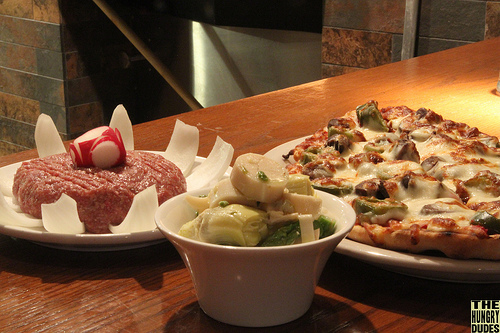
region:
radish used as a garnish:
[69, 118, 131, 171]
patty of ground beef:
[8, 148, 189, 223]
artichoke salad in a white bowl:
[152, 150, 357, 323]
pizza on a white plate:
[246, 87, 496, 284]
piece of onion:
[38, 188, 84, 239]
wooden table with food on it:
[0, 27, 497, 332]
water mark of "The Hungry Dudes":
[471, 300, 499, 332]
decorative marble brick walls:
[0, 3, 117, 153]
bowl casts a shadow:
[148, 290, 383, 332]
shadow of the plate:
[4, 230, 192, 295]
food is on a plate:
[4, 113, 233, 231]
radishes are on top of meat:
[72, 124, 118, 166]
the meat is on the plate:
[20, 143, 178, 225]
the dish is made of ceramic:
[157, 150, 356, 329]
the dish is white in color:
[153, 177, 352, 326]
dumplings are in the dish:
[187, 153, 314, 243]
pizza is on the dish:
[259, 98, 495, 255]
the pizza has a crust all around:
[290, 95, 498, 255]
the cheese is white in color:
[345, 133, 499, 223]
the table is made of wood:
[8, 38, 493, 331]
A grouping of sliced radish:
[62, 124, 132, 168]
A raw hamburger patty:
[8, 136, 188, 221]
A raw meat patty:
[10, 138, 196, 226]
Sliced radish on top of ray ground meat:
[22, 124, 182, 196]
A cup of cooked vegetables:
[161, 148, 358, 322]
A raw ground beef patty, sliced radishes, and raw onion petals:
[0, 102, 223, 238]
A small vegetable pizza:
[349, 96, 491, 265]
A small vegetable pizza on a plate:
[267, 95, 495, 270]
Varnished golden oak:
[412, 54, 493, 107]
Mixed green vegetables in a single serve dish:
[169, 151, 351, 322]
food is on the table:
[35, 97, 449, 277]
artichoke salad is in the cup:
[187, 167, 365, 316]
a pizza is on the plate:
[272, 120, 480, 283]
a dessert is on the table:
[33, 129, 209, 303]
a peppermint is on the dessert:
[47, 126, 173, 183]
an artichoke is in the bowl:
[213, 165, 391, 312]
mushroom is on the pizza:
[324, 155, 481, 271]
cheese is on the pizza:
[328, 158, 475, 290]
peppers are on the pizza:
[304, 135, 487, 252]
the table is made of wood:
[45, 296, 105, 318]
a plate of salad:
[159, 146, 373, 318]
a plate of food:
[3, 120, 240, 255]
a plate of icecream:
[267, 105, 491, 331]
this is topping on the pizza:
[349, 91, 392, 139]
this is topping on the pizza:
[344, 192, 416, 240]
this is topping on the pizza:
[392, 126, 432, 185]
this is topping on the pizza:
[466, 193, 496, 250]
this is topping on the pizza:
[361, 168, 411, 234]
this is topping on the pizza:
[399, 103, 446, 144]